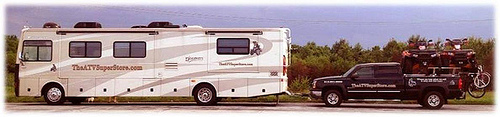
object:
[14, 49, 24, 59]
mirror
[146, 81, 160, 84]
spot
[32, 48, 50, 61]
driver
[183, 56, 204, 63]
words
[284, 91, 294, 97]
tow bar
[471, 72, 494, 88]
wheel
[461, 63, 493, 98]
bicycle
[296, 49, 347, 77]
forest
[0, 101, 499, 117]
road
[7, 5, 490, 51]
sky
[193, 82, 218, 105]
wheel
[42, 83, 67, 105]
wheel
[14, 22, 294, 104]
rv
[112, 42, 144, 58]
window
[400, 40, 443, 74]
atv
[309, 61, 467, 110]
truck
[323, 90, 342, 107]
wheel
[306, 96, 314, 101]
connector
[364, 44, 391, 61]
trees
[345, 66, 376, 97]
door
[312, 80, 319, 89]
lights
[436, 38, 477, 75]
four wheelers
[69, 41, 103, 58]
windows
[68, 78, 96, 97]
squares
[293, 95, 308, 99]
chain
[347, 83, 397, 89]
writing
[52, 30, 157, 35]
bumper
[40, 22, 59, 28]
lights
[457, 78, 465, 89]
tailights